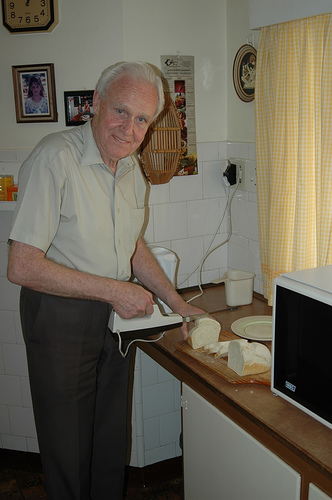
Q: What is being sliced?
A: Bread.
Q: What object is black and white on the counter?
A: Microwave.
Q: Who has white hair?
A: The man.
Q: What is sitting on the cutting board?
A: Bread.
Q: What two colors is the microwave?
A: White and black.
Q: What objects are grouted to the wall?
A: Tiles.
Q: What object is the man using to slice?
A: Electric slicer.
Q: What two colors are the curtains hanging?
A: Yellow and white.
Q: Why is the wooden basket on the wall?
A: It has been hung up.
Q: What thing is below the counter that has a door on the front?
A: Cabinet.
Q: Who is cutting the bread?
A: Old man.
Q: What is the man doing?
A: Cutting bread.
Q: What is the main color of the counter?
A: Brown.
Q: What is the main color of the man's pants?
A: Brown.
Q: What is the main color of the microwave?
A: Black and white.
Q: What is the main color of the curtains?
A: Yellow and white.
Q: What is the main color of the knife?
A: White.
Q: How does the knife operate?
A: Electrical outlet.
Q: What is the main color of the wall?
A: White.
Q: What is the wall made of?
A: Tile.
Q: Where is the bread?
A: Cutting board.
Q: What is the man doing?
A: Cutting bread.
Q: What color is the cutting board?
A: Brown.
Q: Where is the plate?
A: On counter.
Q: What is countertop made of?
A: Wood.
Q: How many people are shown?
A: One.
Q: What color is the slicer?
A: White.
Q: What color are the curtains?
A: Yellow.